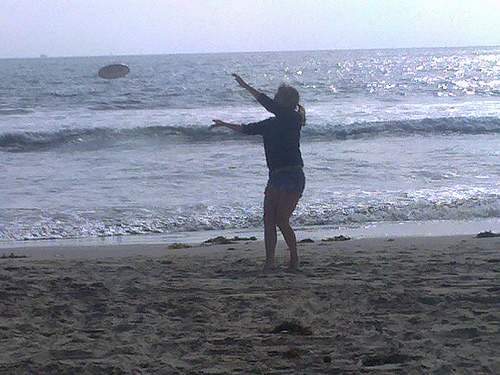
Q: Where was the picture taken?
A: It was taken at the beach.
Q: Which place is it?
A: It is a beach.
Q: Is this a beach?
A: Yes, it is a beach.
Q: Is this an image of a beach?
A: Yes, it is showing a beach.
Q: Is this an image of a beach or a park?
A: It is showing a beach.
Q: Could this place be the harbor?
A: No, it is the beach.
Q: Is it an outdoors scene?
A: Yes, it is outdoors.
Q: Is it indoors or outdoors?
A: It is outdoors.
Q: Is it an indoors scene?
A: No, it is outdoors.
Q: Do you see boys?
A: No, there are no boys.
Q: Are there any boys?
A: No, there are no boys.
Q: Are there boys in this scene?
A: No, there are no boys.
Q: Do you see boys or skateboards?
A: No, there are no boys or skateboards.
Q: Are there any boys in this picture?
A: No, there are no boys.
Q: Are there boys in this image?
A: No, there are no boys.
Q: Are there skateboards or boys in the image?
A: No, there are no boys or skateboards.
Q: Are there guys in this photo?
A: No, there are no guys.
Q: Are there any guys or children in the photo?
A: No, there are no guys or children.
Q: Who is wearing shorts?
A: The lady is wearing shorts.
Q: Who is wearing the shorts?
A: The lady is wearing shorts.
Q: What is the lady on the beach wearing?
A: The lady is wearing shorts.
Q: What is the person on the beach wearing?
A: The lady is wearing shorts.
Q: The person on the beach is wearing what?
A: The lady is wearing shorts.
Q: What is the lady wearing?
A: The lady is wearing shorts.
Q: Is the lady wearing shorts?
A: Yes, the lady is wearing shorts.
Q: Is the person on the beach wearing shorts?
A: Yes, the lady is wearing shorts.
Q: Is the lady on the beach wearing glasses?
A: No, the lady is wearing shorts.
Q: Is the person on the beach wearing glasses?
A: No, the lady is wearing shorts.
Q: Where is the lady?
A: The lady is on the beach.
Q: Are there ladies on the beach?
A: Yes, there is a lady on the beach.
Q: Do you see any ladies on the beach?
A: Yes, there is a lady on the beach.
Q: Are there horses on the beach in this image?
A: No, there is a lady on the beach.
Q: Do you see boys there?
A: No, there are no boys.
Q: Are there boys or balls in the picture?
A: No, there are no boys or balls.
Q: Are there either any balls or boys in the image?
A: No, there are no boys or balls.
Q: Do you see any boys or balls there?
A: No, there are no boys or balls.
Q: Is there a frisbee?
A: Yes, there is a frisbee.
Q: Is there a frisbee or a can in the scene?
A: Yes, there is a frisbee.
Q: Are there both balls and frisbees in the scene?
A: No, there is a frisbee but no balls.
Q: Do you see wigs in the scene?
A: No, there are no wigs.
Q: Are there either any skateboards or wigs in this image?
A: No, there are no wigs or skateboards.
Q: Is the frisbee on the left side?
A: Yes, the frisbee is on the left of the image.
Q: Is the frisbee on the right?
A: No, the frisbee is on the left of the image.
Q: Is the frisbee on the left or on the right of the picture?
A: The frisbee is on the left of the image.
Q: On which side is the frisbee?
A: The frisbee is on the left of the image.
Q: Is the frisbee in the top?
A: Yes, the frisbee is in the top of the image.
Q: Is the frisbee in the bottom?
A: No, the frisbee is in the top of the image.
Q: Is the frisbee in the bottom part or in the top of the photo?
A: The frisbee is in the top of the image.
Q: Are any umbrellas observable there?
A: No, there are no umbrellas.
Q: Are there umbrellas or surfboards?
A: No, there are no umbrellas or surfboards.